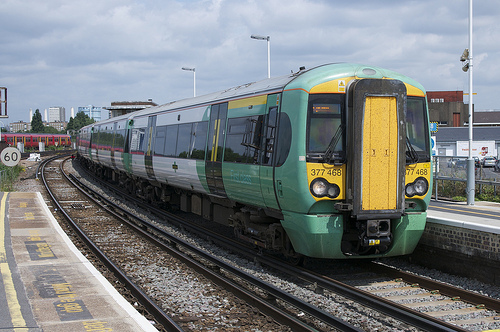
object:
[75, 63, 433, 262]
train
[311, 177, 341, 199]
headlights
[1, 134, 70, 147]
train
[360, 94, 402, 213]
door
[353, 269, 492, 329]
gravel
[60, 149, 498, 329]
tracks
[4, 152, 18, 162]
number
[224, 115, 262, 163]
windows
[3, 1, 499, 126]
sky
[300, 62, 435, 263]
train front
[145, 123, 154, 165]
stripes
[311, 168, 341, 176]
numbers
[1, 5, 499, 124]
clouds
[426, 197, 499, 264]
platform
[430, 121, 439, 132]
sign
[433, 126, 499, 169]
building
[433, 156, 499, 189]
parking lot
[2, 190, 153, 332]
platform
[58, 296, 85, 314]
writing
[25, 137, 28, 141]
windows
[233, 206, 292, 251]
engie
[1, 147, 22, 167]
sign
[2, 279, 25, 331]
line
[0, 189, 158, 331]
sidewalk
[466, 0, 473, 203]
pole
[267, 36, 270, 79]
pole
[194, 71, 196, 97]
pole